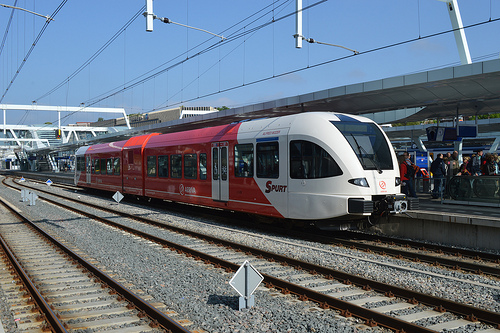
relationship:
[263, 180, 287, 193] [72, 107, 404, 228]
word on train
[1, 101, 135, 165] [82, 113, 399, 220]
overpass over train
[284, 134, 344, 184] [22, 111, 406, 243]
window on train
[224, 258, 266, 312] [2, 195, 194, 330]
sign between track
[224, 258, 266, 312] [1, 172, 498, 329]
sign between track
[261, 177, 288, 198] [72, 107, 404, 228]
word printed on train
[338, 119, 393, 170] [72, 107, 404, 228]
window on train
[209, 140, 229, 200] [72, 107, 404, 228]
door on side of train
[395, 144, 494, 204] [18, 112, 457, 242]
people waiting for train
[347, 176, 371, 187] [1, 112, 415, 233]
light on front of train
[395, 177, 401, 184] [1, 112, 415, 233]
train light on front of train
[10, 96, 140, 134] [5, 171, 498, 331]
metal over tracks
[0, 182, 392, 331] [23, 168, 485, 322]
gravel between tracks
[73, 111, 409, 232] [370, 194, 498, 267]
short train boarding platform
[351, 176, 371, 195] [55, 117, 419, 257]
light on front of train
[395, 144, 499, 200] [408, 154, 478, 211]
people at platform